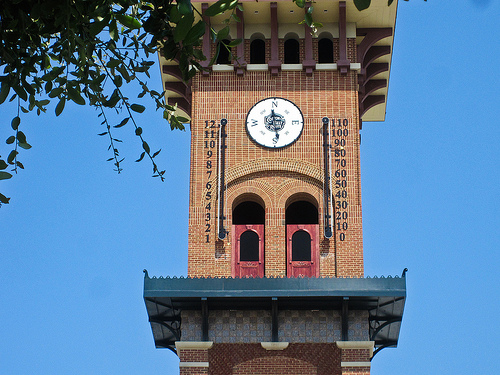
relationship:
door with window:
[232, 224, 265, 279] [231, 192, 263, 224]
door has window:
[232, 224, 265, 279] [286, 191, 318, 225]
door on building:
[282, 226, 320, 285] [137, 0, 401, 374]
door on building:
[236, 216, 263, 273] [137, 0, 401, 374]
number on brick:
[327, 117, 354, 128] [213, 73, 358, 278]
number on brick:
[331, 142, 348, 160] [213, 73, 358, 278]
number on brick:
[335, 198, 349, 210] [213, 73, 358, 278]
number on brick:
[334, 178, 351, 190] [213, 73, 358, 278]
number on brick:
[336, 230, 352, 245] [213, 73, 358, 278]